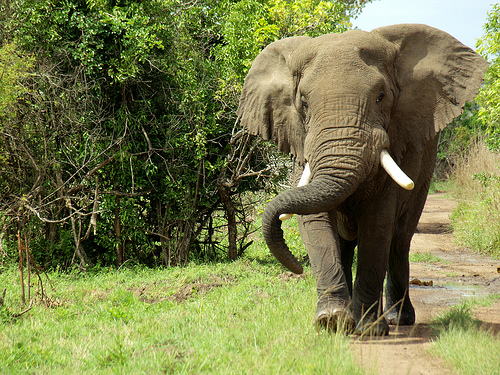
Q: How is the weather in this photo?
A: It is clear.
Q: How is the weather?
A: It is clear.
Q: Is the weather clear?
A: Yes, it is clear.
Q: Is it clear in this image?
A: Yes, it is clear.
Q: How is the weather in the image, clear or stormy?
A: It is clear.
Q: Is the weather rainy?
A: No, it is clear.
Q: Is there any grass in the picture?
A: Yes, there is grass.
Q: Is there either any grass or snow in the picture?
A: Yes, there is grass.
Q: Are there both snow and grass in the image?
A: No, there is grass but no snow.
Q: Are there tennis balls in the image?
A: No, there are no tennis balls.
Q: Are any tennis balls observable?
A: No, there are no tennis balls.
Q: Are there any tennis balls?
A: No, there are no tennis balls.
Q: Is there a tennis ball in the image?
A: No, there are no tennis balls.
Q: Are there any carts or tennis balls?
A: No, there are no tennis balls or carts.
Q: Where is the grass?
A: The grass is on the ground.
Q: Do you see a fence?
A: No, there are no fences.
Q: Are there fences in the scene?
A: No, there are no fences.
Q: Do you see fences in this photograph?
A: No, there are no fences.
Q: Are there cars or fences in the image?
A: No, there are no fences or cars.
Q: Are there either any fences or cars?
A: No, there are no fences or cars.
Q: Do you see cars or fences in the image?
A: No, there are no fences or cars.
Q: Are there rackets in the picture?
A: No, there are no rackets.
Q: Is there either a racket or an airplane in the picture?
A: No, there are no rackets or airplanes.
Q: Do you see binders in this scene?
A: No, there are no binders.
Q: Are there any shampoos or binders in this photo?
A: No, there are no binders or shampoos.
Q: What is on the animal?
A: The trunk is on the animal.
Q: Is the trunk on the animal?
A: Yes, the trunk is on the animal.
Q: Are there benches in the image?
A: No, there are no benches.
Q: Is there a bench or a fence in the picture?
A: No, there are no benches or fences.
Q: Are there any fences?
A: No, there are no fences.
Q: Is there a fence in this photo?
A: No, there are no fences.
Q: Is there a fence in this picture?
A: No, there are no fences.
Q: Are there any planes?
A: No, there are no planes.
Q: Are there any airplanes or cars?
A: No, there are no airplanes or cars.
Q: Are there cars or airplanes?
A: No, there are no airplanes or cars.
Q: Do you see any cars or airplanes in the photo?
A: No, there are no airplanes or cars.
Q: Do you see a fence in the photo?
A: No, there are no fences.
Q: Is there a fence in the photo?
A: No, there are no fences.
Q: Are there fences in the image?
A: No, there are no fences.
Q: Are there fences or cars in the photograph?
A: No, there are no fences or cars.